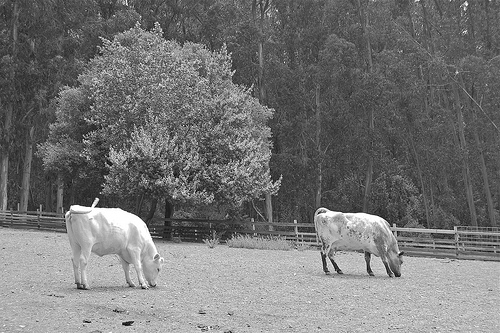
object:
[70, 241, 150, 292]
four legs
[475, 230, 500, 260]
fence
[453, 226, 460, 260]
post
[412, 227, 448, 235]
slats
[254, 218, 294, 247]
fence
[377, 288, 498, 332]
field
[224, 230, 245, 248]
plants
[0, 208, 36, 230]
fence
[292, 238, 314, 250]
plants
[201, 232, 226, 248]
plants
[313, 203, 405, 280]
pig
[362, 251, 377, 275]
legs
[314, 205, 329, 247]
tail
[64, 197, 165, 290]
cow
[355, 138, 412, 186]
ground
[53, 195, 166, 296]
pig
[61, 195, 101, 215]
tail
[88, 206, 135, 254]
body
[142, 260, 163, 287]
face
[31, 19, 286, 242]
tree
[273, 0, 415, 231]
forest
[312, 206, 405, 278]
cows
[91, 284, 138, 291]
shadow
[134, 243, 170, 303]
head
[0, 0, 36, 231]
forest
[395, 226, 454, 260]
fence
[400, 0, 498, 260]
forest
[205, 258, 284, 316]
ground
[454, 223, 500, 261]
fence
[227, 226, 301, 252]
grass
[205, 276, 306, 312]
surface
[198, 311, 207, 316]
rocks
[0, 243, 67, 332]
grass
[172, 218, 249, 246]
fence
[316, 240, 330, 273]
legs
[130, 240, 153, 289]
leg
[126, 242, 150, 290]
leg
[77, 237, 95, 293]
leg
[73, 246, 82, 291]
leg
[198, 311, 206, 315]
rock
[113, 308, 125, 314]
rock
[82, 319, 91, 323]
rock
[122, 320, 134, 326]
rock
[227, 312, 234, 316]
rock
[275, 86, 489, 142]
background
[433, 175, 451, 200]
part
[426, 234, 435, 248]
part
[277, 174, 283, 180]
edge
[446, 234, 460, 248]
part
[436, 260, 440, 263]
edge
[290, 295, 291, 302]
part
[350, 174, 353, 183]
part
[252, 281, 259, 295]
part